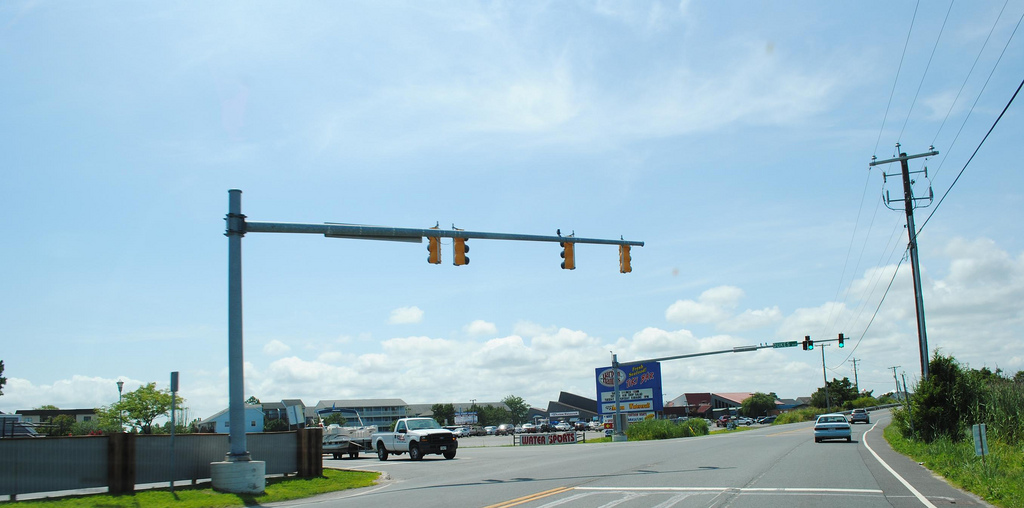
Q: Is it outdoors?
A: Yes, it is outdoors.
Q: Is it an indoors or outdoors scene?
A: It is outdoors.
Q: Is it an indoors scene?
A: No, it is outdoors.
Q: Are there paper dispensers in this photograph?
A: No, there are no paper dispensers.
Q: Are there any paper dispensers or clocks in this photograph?
A: No, there are no paper dispensers or clocks.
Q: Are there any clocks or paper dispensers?
A: No, there are no paper dispensers or clocks.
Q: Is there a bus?
A: No, there are no buses.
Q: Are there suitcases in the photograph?
A: No, there are no suitcases.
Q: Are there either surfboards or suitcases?
A: No, there are no suitcases or surfboards.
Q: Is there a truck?
A: Yes, there is a truck.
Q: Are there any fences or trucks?
A: Yes, there is a truck.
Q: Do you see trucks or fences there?
A: Yes, there is a truck.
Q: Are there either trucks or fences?
A: Yes, there is a truck.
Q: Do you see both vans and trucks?
A: No, there is a truck but no vans.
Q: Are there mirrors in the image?
A: No, there are no mirrors.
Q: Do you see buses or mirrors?
A: No, there are no mirrors or buses.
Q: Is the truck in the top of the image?
A: No, the truck is in the bottom of the image.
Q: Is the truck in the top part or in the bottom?
A: The truck is in the bottom of the image.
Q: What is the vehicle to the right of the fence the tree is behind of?
A: The vehicle is a truck.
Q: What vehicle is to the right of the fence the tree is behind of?
A: The vehicle is a truck.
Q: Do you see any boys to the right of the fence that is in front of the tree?
A: No, there is a truck to the right of the fence.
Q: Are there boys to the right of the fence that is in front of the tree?
A: No, there is a truck to the right of the fence.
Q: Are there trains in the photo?
A: No, there are no trains.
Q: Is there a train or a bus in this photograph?
A: No, there are no trains or buses.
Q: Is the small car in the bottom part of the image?
A: Yes, the car is in the bottom of the image.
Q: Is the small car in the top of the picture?
A: No, the car is in the bottom of the image.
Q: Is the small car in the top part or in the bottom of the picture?
A: The car is in the bottom of the image.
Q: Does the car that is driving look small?
A: Yes, the car is small.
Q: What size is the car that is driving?
A: The car is small.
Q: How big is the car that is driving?
A: The car is small.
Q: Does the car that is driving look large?
A: No, the car is small.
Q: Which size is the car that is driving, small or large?
A: The car is small.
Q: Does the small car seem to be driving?
A: Yes, the car is driving.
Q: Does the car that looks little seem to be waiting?
A: No, the car is driving.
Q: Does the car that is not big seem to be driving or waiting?
A: The car is driving.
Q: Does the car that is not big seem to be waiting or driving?
A: The car is driving.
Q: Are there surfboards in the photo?
A: No, there are no surfboards.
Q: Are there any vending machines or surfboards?
A: No, there are no surfboards or vending machines.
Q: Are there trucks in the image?
A: Yes, there is a truck.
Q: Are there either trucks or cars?
A: Yes, there is a truck.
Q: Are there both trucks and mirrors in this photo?
A: No, there is a truck but no mirrors.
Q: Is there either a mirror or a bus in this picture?
A: No, there are no buses or mirrors.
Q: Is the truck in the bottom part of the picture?
A: Yes, the truck is in the bottom of the image.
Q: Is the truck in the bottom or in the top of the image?
A: The truck is in the bottom of the image.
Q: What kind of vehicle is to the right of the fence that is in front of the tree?
A: The vehicle is a truck.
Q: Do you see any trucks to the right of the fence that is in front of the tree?
A: Yes, there is a truck to the right of the fence.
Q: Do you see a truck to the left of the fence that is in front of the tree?
A: No, the truck is to the right of the fence.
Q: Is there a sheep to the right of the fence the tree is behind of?
A: No, there is a truck to the right of the fence.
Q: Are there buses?
A: No, there are no buses.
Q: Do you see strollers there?
A: No, there are no strollers.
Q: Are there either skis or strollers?
A: No, there are no strollers or skis.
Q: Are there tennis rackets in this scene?
A: No, there are no tennis rackets.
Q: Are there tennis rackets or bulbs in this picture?
A: No, there are no tennis rackets or bulbs.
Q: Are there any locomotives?
A: No, there are no locomotives.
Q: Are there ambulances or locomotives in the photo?
A: No, there are no locomotives or ambulances.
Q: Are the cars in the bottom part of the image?
A: Yes, the cars are in the bottom of the image.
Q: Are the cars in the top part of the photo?
A: No, the cars are in the bottom of the image.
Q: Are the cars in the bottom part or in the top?
A: The cars are in the bottom of the image.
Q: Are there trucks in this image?
A: Yes, there is a truck.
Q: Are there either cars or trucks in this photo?
A: Yes, there is a truck.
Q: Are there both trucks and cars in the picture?
A: Yes, there are both a truck and a car.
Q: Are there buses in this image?
A: No, there are no buses.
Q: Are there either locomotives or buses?
A: No, there are no buses or locomotives.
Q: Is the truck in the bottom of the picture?
A: Yes, the truck is in the bottom of the image.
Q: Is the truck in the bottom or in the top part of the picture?
A: The truck is in the bottom of the image.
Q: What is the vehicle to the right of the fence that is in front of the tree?
A: The vehicle is a truck.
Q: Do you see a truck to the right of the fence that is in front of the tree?
A: Yes, there is a truck to the right of the fence.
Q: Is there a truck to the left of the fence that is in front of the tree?
A: No, the truck is to the right of the fence.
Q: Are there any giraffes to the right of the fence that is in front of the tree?
A: No, there is a truck to the right of the fence.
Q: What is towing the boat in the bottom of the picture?
A: The truck is towing the boat.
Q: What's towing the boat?
A: The truck is towing the boat.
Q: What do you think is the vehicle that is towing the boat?
A: The vehicle is a truck.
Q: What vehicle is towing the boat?
A: The vehicle is a truck.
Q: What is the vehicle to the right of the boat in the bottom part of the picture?
A: The vehicle is a truck.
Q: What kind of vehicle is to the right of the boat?
A: The vehicle is a truck.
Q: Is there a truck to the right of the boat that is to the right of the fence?
A: Yes, there is a truck to the right of the boat.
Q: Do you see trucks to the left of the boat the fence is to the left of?
A: No, the truck is to the right of the boat.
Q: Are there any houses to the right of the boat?
A: No, there is a truck to the right of the boat.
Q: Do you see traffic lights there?
A: Yes, there is a traffic light.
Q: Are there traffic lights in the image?
A: Yes, there is a traffic light.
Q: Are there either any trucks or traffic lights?
A: Yes, there is a traffic light.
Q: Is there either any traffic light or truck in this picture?
A: Yes, there is a traffic light.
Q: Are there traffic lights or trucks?
A: Yes, there is a traffic light.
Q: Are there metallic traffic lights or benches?
A: Yes, there is a metal traffic light.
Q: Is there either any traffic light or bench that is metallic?
A: Yes, the traffic light is metallic.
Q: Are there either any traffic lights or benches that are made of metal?
A: Yes, the traffic light is made of metal.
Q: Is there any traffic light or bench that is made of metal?
A: Yes, the traffic light is made of metal.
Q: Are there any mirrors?
A: No, there are no mirrors.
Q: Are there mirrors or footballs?
A: No, there are no mirrors or footballs.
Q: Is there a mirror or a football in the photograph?
A: No, there are no mirrors or footballs.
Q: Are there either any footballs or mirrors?
A: No, there are no mirrors or footballs.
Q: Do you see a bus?
A: No, there are no buses.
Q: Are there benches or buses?
A: No, there are no buses or benches.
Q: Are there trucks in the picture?
A: Yes, there is a truck.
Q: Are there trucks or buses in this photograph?
A: Yes, there is a truck.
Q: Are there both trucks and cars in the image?
A: Yes, there are both a truck and a car.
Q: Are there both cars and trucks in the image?
A: Yes, there are both a truck and a car.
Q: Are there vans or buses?
A: No, there are no buses or vans.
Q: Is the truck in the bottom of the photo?
A: Yes, the truck is in the bottom of the image.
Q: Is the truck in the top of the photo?
A: No, the truck is in the bottom of the image.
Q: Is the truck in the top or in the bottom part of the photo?
A: The truck is in the bottom of the image.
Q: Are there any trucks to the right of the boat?
A: Yes, there is a truck to the right of the boat.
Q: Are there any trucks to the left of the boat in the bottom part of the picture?
A: No, the truck is to the right of the boat.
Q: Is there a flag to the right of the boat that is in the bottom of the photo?
A: No, there is a truck to the right of the boat.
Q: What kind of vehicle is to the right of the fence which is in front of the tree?
A: The vehicle is a truck.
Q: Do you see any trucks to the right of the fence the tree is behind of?
A: Yes, there is a truck to the right of the fence.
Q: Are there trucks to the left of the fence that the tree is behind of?
A: No, the truck is to the right of the fence.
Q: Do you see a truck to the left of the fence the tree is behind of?
A: No, the truck is to the right of the fence.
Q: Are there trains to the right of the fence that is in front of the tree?
A: No, there is a truck to the right of the fence.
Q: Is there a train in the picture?
A: No, there are no trains.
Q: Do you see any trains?
A: No, there are no trains.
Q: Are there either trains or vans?
A: No, there are no trains or vans.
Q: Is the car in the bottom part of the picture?
A: Yes, the car is in the bottom of the image.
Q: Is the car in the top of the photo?
A: No, the car is in the bottom of the image.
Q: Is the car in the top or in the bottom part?
A: The car is in the bottom of the image.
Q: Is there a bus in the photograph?
A: No, there are no buses.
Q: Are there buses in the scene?
A: No, there are no buses.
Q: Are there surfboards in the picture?
A: No, there are no surfboards.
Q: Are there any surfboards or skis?
A: No, there are no surfboards or skis.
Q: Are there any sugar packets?
A: No, there are no sugar packets.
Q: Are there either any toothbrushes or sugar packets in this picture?
A: No, there are no sugar packets or toothbrushes.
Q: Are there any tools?
A: No, there are no tools.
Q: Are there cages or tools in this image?
A: No, there are no tools or cages.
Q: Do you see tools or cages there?
A: No, there are no tools or cages.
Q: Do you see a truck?
A: Yes, there is a truck.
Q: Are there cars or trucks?
A: Yes, there is a truck.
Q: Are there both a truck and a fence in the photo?
A: Yes, there are both a truck and a fence.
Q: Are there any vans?
A: No, there are no vans.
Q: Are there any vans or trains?
A: No, there are no vans or trains.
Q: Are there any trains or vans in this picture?
A: No, there are no vans or trains.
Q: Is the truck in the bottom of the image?
A: Yes, the truck is in the bottom of the image.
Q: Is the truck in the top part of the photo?
A: No, the truck is in the bottom of the image.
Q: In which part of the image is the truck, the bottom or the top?
A: The truck is in the bottom of the image.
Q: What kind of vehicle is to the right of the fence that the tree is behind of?
A: The vehicle is a truck.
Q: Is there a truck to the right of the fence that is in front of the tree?
A: Yes, there is a truck to the right of the fence.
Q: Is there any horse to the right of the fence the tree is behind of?
A: No, there is a truck to the right of the fence.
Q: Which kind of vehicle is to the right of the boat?
A: The vehicle is a truck.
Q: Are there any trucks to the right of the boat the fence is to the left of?
A: Yes, there is a truck to the right of the boat.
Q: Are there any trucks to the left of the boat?
A: No, the truck is to the right of the boat.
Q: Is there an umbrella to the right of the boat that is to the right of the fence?
A: No, there is a truck to the right of the boat.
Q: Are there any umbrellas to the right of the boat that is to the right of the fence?
A: No, there is a truck to the right of the boat.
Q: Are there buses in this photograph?
A: No, there are no buses.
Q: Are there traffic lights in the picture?
A: Yes, there is a traffic light.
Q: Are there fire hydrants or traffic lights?
A: Yes, there is a traffic light.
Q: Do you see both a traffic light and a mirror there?
A: No, there is a traffic light but no mirrors.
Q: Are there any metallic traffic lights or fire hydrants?
A: Yes, there is a metal traffic light.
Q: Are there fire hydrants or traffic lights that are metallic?
A: Yes, the traffic light is metallic.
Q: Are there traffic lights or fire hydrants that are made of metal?
A: Yes, the traffic light is made of metal.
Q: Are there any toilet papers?
A: No, there are no toilet papers.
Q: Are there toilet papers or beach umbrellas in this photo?
A: No, there are no toilet papers or beach umbrellas.